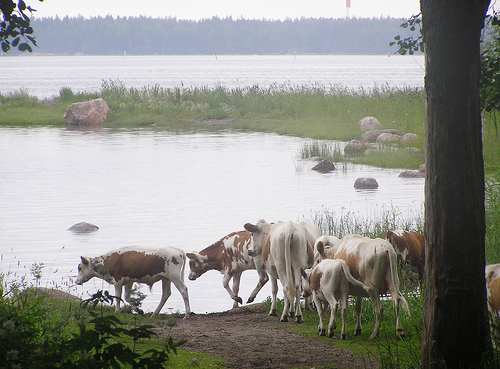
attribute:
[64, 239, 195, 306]
cow — brown, white, spotted, walking, bronw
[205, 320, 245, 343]
trail — brown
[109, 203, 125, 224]
water — gray, wet, white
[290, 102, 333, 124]
grass — green, tall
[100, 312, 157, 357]
plant — green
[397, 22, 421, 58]
tree — green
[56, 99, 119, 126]
rock — large